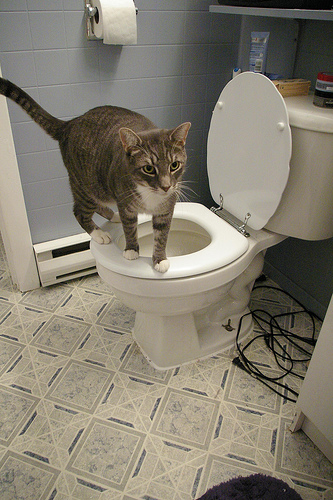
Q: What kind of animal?
A: Cat.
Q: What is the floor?
A: Tile.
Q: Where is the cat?
A: Toilet.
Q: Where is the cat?
A: In the bathroom.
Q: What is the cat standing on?
A: A toilet.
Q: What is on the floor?
A: A chord.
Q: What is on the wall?
A: Toilet paper.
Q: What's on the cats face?
A: Whiskers.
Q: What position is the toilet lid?
A: Open.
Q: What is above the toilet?
A: A shelf.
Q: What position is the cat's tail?
A: Sticking out.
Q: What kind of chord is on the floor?
A: Electrical.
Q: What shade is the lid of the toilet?
A: White.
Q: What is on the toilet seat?
A: White paws of a cat.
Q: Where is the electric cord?
A: On bathroom floor.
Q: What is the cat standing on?
A: Bathroom toilet.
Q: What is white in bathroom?
A: Toilet.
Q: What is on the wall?
A: Square tiles.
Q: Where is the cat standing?
A: On the western toilet.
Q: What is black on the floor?
A: Some cable.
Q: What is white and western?
A: Toilet and flush tank.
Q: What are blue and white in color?
A: Floor tiles.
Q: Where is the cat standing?
A: Toilet.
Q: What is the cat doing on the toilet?
A: Walking.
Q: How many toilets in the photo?
A: One.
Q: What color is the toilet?
A: White.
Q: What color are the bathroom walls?
A: Blue.